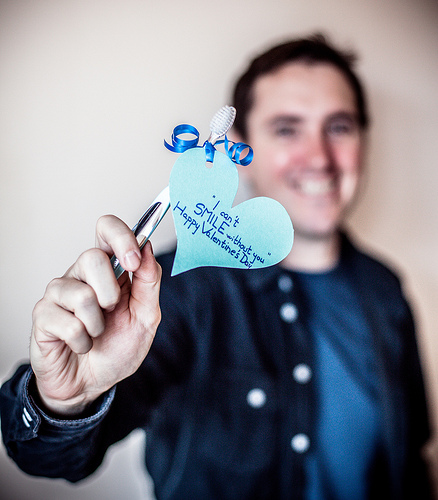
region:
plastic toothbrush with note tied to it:
[75, 105, 300, 307]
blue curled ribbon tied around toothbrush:
[156, 115, 259, 167]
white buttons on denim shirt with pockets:
[234, 345, 337, 465]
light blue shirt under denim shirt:
[297, 335, 402, 450]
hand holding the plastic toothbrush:
[19, 201, 181, 438]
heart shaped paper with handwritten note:
[161, 141, 306, 289]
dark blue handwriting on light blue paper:
[169, 190, 275, 272]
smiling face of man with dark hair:
[214, 25, 389, 262]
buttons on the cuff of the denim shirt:
[9, 392, 54, 440]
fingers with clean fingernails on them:
[24, 223, 146, 365]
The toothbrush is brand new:
[97, 102, 296, 310]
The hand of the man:
[20, 213, 163, 413]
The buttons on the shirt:
[277, 292, 315, 469]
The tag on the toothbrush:
[160, 123, 297, 283]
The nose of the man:
[303, 131, 335, 171]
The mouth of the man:
[296, 170, 341, 200]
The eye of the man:
[269, 119, 303, 143]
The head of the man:
[219, 32, 377, 245]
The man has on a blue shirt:
[305, 273, 374, 498]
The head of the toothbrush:
[205, 99, 238, 141]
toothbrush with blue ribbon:
[134, 117, 259, 242]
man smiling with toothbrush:
[217, 48, 396, 242]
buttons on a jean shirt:
[275, 284, 315, 456]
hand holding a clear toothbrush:
[19, 222, 192, 390]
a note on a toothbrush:
[173, 149, 293, 274]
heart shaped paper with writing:
[168, 135, 306, 286]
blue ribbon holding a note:
[166, 122, 266, 170]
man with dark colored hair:
[216, 48, 381, 236]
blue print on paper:
[164, 187, 272, 272]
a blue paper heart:
[168, 149, 293, 277]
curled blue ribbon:
[160, 124, 253, 165]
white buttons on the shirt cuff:
[21, 410, 31, 427]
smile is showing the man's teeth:
[290, 167, 340, 199]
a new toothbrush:
[111, 104, 236, 272]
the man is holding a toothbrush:
[35, 105, 235, 399]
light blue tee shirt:
[294, 270, 385, 495]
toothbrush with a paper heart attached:
[111, 105, 294, 272]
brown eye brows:
[269, 110, 354, 125]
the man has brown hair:
[229, 31, 365, 231]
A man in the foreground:
[0, 27, 437, 497]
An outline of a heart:
[155, 137, 305, 303]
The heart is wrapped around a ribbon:
[140, 120, 306, 294]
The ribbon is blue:
[159, 114, 264, 178]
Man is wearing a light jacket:
[4, 220, 435, 498]